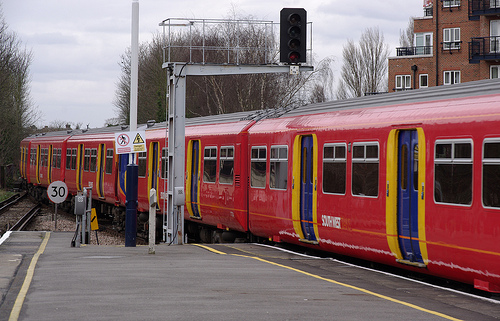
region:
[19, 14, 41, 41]
white clouds in blue sky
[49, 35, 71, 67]
white clouds in blue sky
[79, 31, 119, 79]
white clouds in blue sky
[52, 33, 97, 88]
white clouds in blue sky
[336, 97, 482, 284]
red and yellow passenger train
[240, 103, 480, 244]
red and yellow passenger train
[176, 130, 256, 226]
red and yellow passenger train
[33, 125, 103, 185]
red and yellow passenger train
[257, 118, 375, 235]
red and yellow passenger train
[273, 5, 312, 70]
The light is black.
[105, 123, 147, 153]
The sign is white.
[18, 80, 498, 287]
The train is red.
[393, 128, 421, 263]
The door is blue.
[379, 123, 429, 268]
The edge of the door is yellow.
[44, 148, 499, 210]
The windows are on the side.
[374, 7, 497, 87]
The building is brick.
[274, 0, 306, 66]
The light is off.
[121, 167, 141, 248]
The pole is blue.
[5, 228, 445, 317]
The waiting area is concrete.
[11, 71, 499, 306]
train next to a platform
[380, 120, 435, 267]
doors on a train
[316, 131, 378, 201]
windows on a train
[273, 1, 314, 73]
signals over a train track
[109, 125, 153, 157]
signs on a pole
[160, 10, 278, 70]
hand rails on a signal platform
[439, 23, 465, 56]
windows on a building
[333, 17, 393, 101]
trees behind a train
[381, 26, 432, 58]
balcony on a building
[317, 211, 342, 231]
white lettering on a train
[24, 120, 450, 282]
the train is red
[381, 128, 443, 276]
the door is blue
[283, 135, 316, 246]
the door is blue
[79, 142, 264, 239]
the door is blue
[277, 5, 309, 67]
A black, unlit traffic signal.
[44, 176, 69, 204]
A red and white sign with a black 30 on it.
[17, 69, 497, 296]
A red, yellow and blue multi car train.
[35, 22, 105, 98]
A patch of cloudy sky.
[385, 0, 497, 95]
A brick building behind the train.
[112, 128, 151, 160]
Two warning signs on a metal pole.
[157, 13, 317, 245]
Silver, metal structure holding up the traffic light.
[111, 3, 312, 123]
A large leafless tree behind the train.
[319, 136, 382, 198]
Windows on the train.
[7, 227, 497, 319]
An asphalt road next to the train.